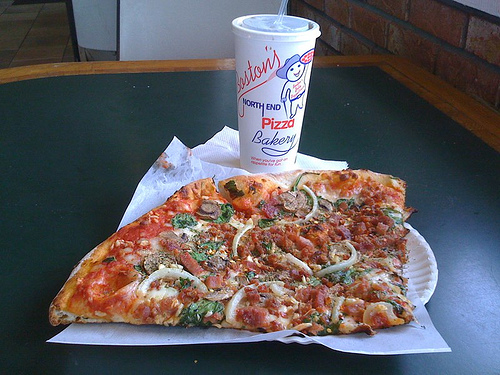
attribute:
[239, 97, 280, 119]
north end — blue letters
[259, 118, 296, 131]
word pizza — red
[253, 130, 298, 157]
bakery — blue letters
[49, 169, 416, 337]
slices of  pizza — vegetable, large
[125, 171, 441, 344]
plate — paper, white, paper made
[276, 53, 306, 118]
figure — a mascot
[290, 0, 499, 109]
wall — made of bricks, old, brick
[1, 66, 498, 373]
table — gree, large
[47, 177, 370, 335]
pizza — spicy, big, red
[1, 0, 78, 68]
floor — tiled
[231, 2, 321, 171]
cup — large, white